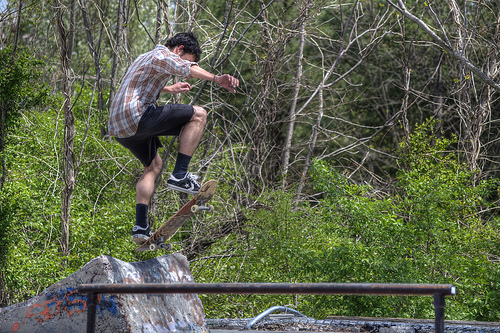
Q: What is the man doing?
A: Skateboard trick.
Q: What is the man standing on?
A: Skateboard.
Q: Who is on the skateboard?
A: A man.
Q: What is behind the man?
A: Trees.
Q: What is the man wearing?
A: Socks.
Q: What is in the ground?
A: Grass.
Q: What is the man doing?
A: Skating.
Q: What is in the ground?
A: Leafs.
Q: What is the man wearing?
A: Shirt.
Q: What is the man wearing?
A: Shorts.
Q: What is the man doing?
A: Jumping.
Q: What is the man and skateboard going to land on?
A: The rail.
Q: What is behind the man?
A: Trees.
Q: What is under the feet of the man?
A: A skateboard.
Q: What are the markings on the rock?
A: Graffiti.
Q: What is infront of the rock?
A: A rail.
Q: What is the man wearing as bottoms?
A: Shorts.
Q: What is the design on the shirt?
A: Plaid.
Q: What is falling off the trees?
A: Leaves.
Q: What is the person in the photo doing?
A: Skateboarding.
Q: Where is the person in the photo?
A: A park.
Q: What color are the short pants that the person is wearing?
A: Black.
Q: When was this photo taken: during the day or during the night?
A: During the day.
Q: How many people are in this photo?
A: One.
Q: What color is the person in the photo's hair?
A: Black.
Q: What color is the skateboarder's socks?
A: Black.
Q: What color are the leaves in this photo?
A: Green.